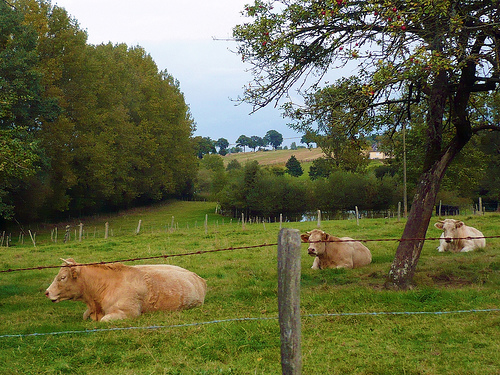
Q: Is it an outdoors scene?
A: Yes, it is outdoors.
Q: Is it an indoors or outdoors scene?
A: It is outdoors.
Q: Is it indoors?
A: No, it is outdoors.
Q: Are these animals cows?
A: Yes, all the animals are cows.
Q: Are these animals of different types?
A: No, all the animals are cows.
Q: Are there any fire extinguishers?
A: No, there are no fire extinguishers.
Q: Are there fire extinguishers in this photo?
A: No, there are no fire extinguishers.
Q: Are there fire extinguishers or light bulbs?
A: No, there are no fire extinguishers or light bulbs.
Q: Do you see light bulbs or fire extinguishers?
A: No, there are no fire extinguishers or light bulbs.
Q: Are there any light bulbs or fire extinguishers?
A: No, there are no fire extinguishers or light bulbs.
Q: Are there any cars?
A: No, there are no cars.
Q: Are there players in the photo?
A: No, there are no players.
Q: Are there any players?
A: No, there are no players.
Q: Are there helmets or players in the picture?
A: No, there are no players or helmets.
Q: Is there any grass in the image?
A: Yes, there is grass.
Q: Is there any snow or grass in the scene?
A: Yes, there is grass.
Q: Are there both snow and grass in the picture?
A: No, there is grass but no snow.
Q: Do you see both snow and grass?
A: No, there is grass but no snow.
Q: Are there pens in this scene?
A: No, there are no pens.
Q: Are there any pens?
A: No, there are no pens.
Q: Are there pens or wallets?
A: No, there are no pens or wallets.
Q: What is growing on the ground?
A: The grass is growing on the ground.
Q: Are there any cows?
A: Yes, there is a cow.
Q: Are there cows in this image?
A: Yes, there is a cow.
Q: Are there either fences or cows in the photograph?
A: Yes, there is a cow.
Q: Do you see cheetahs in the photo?
A: No, there are no cheetahs.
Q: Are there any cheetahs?
A: No, there are no cheetahs.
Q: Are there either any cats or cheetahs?
A: No, there are no cheetahs or cats.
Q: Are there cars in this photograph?
A: No, there are no cars.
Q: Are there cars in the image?
A: No, there are no cars.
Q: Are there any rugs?
A: No, there are no rugs.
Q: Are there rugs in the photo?
A: No, there are no rugs.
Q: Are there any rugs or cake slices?
A: No, there are no rugs or cake slices.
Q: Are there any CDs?
A: No, there are no cds.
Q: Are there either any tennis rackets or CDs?
A: No, there are no CDs or tennis rackets.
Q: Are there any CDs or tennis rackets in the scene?
A: No, there are no CDs or tennis rackets.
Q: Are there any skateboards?
A: No, there are no skateboards.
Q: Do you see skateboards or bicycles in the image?
A: No, there are no skateboards or bicycles.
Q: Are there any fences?
A: Yes, there is a fence.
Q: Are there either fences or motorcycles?
A: Yes, there is a fence.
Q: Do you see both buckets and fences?
A: No, there is a fence but no buckets.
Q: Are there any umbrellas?
A: No, there are no umbrellas.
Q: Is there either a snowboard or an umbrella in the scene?
A: No, there are no umbrellas or snowboards.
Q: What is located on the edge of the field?
A: The fence is on the edge of the field.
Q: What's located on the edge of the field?
A: The fence is on the edge of the field.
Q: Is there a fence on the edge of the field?
A: Yes, there is a fence on the edge of the field.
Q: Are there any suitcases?
A: No, there are no suitcases.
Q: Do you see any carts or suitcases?
A: No, there are no suitcases or carts.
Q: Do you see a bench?
A: No, there are no benches.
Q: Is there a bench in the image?
A: No, there are no benches.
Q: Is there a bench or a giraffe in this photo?
A: No, there are no benches or giraffes.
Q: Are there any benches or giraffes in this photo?
A: No, there are no benches or giraffes.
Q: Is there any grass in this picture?
A: Yes, there is grass.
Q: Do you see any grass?
A: Yes, there is grass.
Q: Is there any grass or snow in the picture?
A: Yes, there is grass.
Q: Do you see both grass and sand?
A: No, there is grass but no sand.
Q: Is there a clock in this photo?
A: No, there are no clocks.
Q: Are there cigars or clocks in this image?
A: No, there are no clocks or cigars.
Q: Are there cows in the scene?
A: Yes, there is a cow.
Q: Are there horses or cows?
A: Yes, there is a cow.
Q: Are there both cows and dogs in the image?
A: No, there is a cow but no dogs.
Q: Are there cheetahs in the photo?
A: No, there are no cheetahs.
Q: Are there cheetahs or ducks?
A: No, there are no cheetahs or ducks.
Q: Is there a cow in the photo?
A: Yes, there are cows.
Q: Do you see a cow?
A: Yes, there are cows.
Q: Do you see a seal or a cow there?
A: Yes, there are cows.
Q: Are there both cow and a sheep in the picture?
A: No, there are cows but no sheep.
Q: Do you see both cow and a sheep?
A: No, there are cows but no sheep.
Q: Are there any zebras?
A: No, there are no zebras.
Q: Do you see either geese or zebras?
A: No, there are no zebras or geese.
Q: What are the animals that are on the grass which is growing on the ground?
A: The animals are cows.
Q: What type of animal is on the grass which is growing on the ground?
A: The animals are cows.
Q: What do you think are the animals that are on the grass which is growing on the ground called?
A: The animals are cows.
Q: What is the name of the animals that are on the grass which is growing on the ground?
A: The animals are cows.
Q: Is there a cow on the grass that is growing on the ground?
A: Yes, there are cows on the grass.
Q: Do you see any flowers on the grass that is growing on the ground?
A: No, there are cows on the grass.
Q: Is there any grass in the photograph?
A: Yes, there is grass.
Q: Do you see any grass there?
A: Yes, there is grass.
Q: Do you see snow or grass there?
A: Yes, there is grass.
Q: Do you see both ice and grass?
A: No, there is grass but no ice.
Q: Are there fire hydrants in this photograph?
A: No, there are no fire hydrants.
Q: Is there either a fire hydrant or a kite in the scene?
A: No, there are no fire hydrants or kites.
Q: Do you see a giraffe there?
A: No, there are no giraffes.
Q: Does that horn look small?
A: Yes, the horn is small.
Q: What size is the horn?
A: The horn is small.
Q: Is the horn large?
A: No, the horn is small.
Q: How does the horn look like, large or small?
A: The horn is small.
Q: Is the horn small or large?
A: The horn is small.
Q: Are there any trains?
A: No, there are no trains.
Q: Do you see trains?
A: No, there are no trains.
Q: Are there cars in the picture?
A: No, there are no cars.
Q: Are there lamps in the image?
A: No, there are no lamps.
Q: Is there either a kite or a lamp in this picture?
A: No, there are no lamps or kites.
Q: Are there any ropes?
A: No, there are no ropes.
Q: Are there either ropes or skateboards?
A: No, there are no ropes or skateboards.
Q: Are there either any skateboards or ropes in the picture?
A: No, there are no ropes or skateboards.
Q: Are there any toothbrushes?
A: No, there are no toothbrushes.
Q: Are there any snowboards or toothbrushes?
A: No, there are no toothbrushes or snowboards.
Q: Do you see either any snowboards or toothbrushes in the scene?
A: No, there are no toothbrushes or snowboards.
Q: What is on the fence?
A: The wire is on the fence.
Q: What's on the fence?
A: The wire is on the fence.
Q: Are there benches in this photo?
A: No, there are no benches.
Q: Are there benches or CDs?
A: No, there are no benches or cds.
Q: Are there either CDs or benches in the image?
A: No, there are no benches or cds.